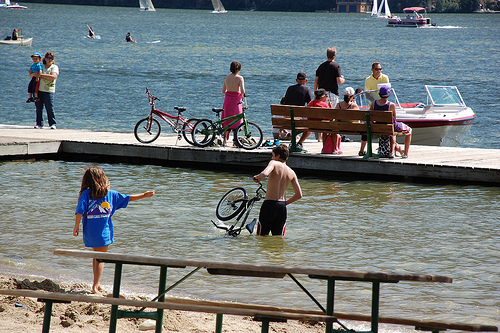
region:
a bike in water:
[211, 180, 261, 243]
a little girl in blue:
[69, 164, 155, 295]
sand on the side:
[2, 272, 369, 332]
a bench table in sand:
[0, 244, 457, 331]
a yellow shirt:
[361, 74, 391, 89]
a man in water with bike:
[213, 140, 303, 242]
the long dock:
[2, 121, 498, 173]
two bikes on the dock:
[130, 84, 264, 151]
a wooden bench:
[266, 102, 404, 159]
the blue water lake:
[3, 4, 499, 144]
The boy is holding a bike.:
[185, 133, 310, 262]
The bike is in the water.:
[208, 140, 306, 262]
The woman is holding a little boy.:
[18, 41, 66, 138]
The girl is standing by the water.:
[0, 148, 207, 330]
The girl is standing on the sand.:
[1, 153, 176, 331]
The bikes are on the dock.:
[103, 56, 268, 159]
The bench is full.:
[261, 60, 410, 165]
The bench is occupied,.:
[263, 72, 418, 169]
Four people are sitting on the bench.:
[260, 58, 418, 160]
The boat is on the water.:
[333, 40, 491, 152]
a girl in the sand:
[52, 143, 158, 328]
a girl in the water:
[50, 138, 160, 325]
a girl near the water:
[54, 145, 171, 328]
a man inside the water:
[217, 119, 337, 301]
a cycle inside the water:
[183, 145, 277, 281]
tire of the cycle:
[201, 179, 271, 245]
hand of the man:
[288, 163, 307, 220]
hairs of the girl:
[85, 160, 117, 194]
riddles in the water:
[163, 203, 204, 255]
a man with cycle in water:
[188, 127, 329, 285]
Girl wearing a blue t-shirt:
[73, 165, 154, 296]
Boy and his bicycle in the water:
[210, 143, 303, 241]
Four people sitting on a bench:
[267, 70, 412, 160]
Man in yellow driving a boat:
[362, 58, 393, 109]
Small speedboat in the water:
[337, 83, 477, 147]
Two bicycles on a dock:
[133, 85, 263, 148]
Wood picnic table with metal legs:
[0, 248, 499, 331]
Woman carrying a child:
[25, 49, 60, 129]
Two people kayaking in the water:
[80, 22, 163, 46]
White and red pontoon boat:
[385, 5, 430, 30]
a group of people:
[21, 32, 490, 169]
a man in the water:
[191, 113, 444, 313]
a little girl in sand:
[52, 122, 197, 300]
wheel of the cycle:
[205, 148, 270, 231]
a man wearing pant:
[259, 180, 314, 245]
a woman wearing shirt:
[28, 60, 84, 112]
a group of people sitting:
[202, 38, 471, 176]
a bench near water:
[249, 90, 458, 170]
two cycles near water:
[136, 72, 276, 152]